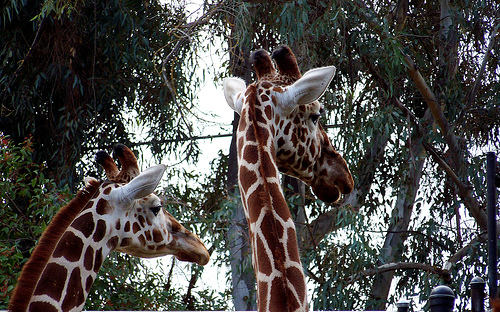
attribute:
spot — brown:
[93, 216, 107, 244]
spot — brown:
[56, 240, 108, 276]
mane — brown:
[246, 84, 290, 308]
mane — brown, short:
[5, 176, 97, 310]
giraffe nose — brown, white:
[333, 160, 355, 190]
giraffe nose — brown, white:
[196, 232, 207, 264]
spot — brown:
[283, 224, 300, 262]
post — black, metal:
[426, 283, 458, 310]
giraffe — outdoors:
[199, 54, 374, 306]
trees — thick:
[0, 0, 190, 142]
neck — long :
[236, 142, 306, 309]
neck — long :
[11, 201, 107, 308]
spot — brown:
[24, 259, 69, 305]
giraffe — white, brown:
[8, 142, 209, 309]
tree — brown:
[349, 23, 497, 300]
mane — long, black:
[216, 114, 319, 264]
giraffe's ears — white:
[221, 59, 343, 119]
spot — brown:
[268, 182, 288, 211]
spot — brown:
[62, 267, 87, 310]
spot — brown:
[248, 227, 278, 280]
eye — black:
[309, 111, 319, 122]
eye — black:
[149, 205, 160, 215]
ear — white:
[284, 64, 335, 106]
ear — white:
[223, 80, 245, 114]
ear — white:
[112, 162, 166, 209]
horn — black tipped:
[271, 43, 301, 80]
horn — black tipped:
[248, 49, 277, 80]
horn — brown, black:
[268, 44, 302, 78]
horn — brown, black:
[249, 49, 279, 83]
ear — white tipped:
[287, 63, 337, 110]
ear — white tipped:
[222, 85, 248, 115]